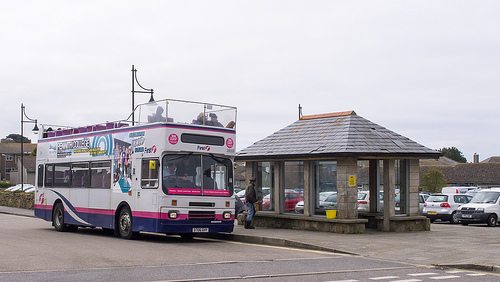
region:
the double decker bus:
[32, 90, 238, 243]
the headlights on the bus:
[167, 205, 231, 222]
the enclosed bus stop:
[235, 104, 427, 235]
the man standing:
[244, 173, 258, 227]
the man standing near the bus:
[242, 176, 259, 224]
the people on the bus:
[162, 155, 200, 190]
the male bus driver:
[162, 160, 178, 180]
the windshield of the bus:
[162, 150, 235, 199]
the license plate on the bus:
[189, 226, 211, 232]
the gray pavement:
[22, 232, 157, 279]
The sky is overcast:
[259, 15, 394, 107]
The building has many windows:
[250, 88, 495, 263]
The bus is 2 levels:
[108, 98, 250, 229]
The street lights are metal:
[1, 85, 106, 237]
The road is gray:
[9, 226, 82, 276]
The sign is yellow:
[343, 163, 358, 192]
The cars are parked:
[412, 153, 497, 225]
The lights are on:
[164, 203, 182, 220]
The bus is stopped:
[16, 107, 236, 279]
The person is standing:
[237, 166, 292, 264]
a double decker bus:
[35, 94, 232, 244]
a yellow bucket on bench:
[308, 199, 349, 238]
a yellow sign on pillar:
[327, 168, 372, 215]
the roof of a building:
[277, 108, 444, 198]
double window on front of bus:
[158, 154, 242, 195]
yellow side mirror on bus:
[127, 153, 162, 193]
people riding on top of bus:
[73, 103, 244, 156]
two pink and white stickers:
[142, 133, 236, 168]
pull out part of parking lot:
[224, 228, 478, 279]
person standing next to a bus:
[177, 175, 289, 247]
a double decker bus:
[8, 70, 336, 280]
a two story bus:
[34, 55, 255, 232]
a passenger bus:
[36, 91, 321, 280]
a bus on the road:
[21, 91, 183, 268]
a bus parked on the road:
[29, 49, 262, 275]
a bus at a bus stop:
[28, 70, 400, 280]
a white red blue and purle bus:
[4, 48, 364, 280]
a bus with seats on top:
[35, 56, 310, 255]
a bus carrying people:
[35, 42, 363, 281]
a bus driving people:
[8, 30, 379, 278]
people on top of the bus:
[36, 55, 296, 274]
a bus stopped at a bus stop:
[74, 63, 381, 277]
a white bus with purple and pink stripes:
[15, 67, 369, 273]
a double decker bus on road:
[12, 47, 302, 281]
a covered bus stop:
[232, 55, 472, 272]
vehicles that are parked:
[335, 93, 481, 228]